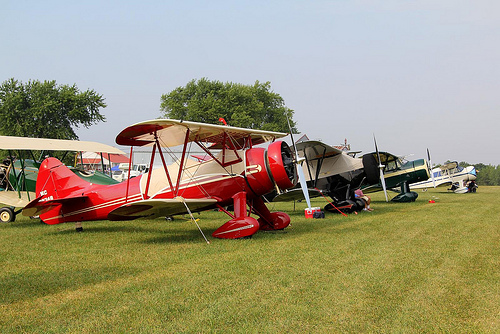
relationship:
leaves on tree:
[156, 73, 303, 130] [163, 76, 299, 133]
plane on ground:
[22, 105, 312, 240] [10, 172, 471, 332]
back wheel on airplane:
[2, 206, 19, 229] [22, 116, 295, 243]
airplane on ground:
[430, 155, 481, 193] [10, 172, 471, 332]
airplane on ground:
[347, 149, 428, 216] [10, 172, 471, 332]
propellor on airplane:
[425, 146, 436, 190] [352, 150, 432, 204]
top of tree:
[245, 70, 277, 94] [156, 71, 325, 191]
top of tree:
[2, 79, 105, 106] [163, 76, 299, 133]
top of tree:
[169, 76, 279, 101] [1, 75, 107, 139]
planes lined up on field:
[50, 90, 478, 267] [9, 180, 482, 332]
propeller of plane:
[367, 132, 392, 203] [292, 128, 390, 218]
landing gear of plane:
[210, 192, 288, 247] [22, 105, 312, 240]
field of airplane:
[9, 180, 482, 332] [11, 118, 306, 237]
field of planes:
[9, 180, 482, 332] [261, 132, 389, 215]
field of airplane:
[9, 180, 482, 332] [367, 147, 432, 201]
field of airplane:
[9, 180, 482, 332] [402, 162, 482, 194]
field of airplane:
[9, 180, 482, 332] [0, 135, 130, 222]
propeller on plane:
[269, 134, 341, 208] [62, 107, 392, 272]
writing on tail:
[35, 188, 52, 202] [32, 156, 122, 221]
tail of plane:
[32, 156, 122, 221] [24, 118, 294, 233]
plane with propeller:
[22, 105, 312, 240] [270, 137, 345, 214]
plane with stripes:
[0, 111, 320, 242] [75, 174, 236, 210]